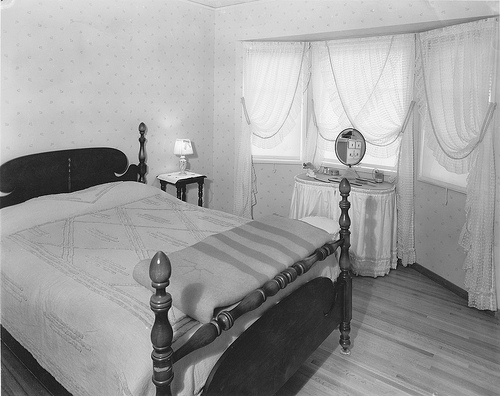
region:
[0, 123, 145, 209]
A dark brown head board.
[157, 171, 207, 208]
A dark brown side table.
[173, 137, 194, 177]
A small white lamp.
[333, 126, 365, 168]
A large oval mirror on a table.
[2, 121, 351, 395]
A large wooden bed.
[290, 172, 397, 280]
A large white table skirt on a table.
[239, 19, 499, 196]
Three windows past a table.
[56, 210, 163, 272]
comforter on the bed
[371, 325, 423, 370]
the wooden floor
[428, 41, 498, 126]
the curtains are white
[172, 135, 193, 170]
a small lamp on the night stand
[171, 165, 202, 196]
a nightstand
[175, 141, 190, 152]
the lamp shade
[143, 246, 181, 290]
edge of bed frame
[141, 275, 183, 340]
pattern on bed frame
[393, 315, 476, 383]
lines on the floor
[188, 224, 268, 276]
folded sheet on the bed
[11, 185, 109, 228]
white pillow on bed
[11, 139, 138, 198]
large black bed head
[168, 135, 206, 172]
small white lamp on table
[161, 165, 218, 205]
black bedside table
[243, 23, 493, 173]
sheer white valance on window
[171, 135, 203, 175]
Black and white portrayal of lamp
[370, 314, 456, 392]
Wooden floor with grains visible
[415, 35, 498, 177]
Draping curtains over a window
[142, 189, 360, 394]
Wooden foot board piece of a bed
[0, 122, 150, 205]
Wooden head rest of a bed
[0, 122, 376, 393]
Bed with white sheets made up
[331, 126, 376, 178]
Small vanity mirror sitting on top of fixture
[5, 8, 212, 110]
Wall with simple wallpaper design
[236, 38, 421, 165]
Window with drapes letting light in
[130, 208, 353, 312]
Striped comforter sitting on top of a bed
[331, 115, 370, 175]
round mirror on oval table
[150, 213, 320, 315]
folded blanket at foot of the bed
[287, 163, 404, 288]
oval table with white cloth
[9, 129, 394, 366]
queen size bed with white cover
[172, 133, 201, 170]
small lamp with white shade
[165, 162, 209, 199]
small wood square table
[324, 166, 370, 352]
wood post on bed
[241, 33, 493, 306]
white curtains on windows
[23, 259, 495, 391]
floors made of hard wood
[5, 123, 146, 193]
headboard on bed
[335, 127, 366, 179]
The circle shape mirror on the table.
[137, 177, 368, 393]
The footboard of the bed.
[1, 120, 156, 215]
The headboard of the bed.